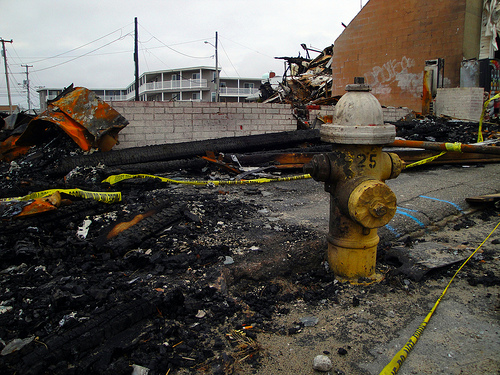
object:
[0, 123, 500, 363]
ground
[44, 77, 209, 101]
balcony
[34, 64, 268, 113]
building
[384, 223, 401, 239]
stripes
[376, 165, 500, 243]
curb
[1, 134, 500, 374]
street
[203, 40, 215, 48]
lamp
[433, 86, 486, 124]
block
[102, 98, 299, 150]
wall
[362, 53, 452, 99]
graffiti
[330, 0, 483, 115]
building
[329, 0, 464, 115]
brick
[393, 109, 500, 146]
charred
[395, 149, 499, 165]
wood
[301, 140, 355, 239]
blackened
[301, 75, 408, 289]
hydrant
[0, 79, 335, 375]
fire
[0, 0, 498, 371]
scene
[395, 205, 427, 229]
stripe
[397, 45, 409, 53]
bricks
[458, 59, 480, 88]
smoke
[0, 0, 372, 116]
background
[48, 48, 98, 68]
lines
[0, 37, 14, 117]
posts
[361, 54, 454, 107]
writing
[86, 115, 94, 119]
remnants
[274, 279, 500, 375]
section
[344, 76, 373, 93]
top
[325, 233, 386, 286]
bottom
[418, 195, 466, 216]
marking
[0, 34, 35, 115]
telephone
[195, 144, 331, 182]
debris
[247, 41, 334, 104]
debris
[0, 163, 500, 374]
area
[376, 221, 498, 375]
police tape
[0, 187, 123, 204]
police tape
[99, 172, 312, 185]
police tape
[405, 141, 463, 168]
police tape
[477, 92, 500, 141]
police tape